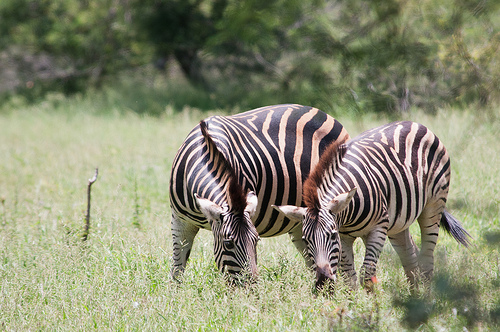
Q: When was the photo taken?
A: Daytime.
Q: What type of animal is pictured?
A: Zebra.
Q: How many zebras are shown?
A: Two.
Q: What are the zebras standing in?
A: Field.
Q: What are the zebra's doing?
A: Eating.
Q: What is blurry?
A: Background.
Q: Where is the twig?
A: Standing in the grass.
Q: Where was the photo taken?
A: In a pasture.